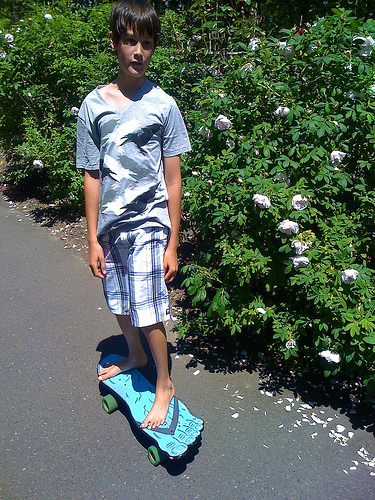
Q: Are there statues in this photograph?
A: No, there are no statues.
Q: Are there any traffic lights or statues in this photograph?
A: No, there are no statues or traffic lights.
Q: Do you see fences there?
A: No, there are no fences.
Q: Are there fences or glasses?
A: No, there are no fences or glasses.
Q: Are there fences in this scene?
A: No, there are no fences.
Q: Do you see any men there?
A: No, there are no men.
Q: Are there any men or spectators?
A: No, there are no men or spectators.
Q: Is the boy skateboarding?
A: Yes, the boy is skateboarding.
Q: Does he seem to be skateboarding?
A: Yes, the boy is skateboarding.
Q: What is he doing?
A: The boy is skateboarding.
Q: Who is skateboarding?
A: The boy is skateboarding.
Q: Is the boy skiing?
A: No, the boy is skateboarding.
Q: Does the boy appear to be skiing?
A: No, the boy is skateboarding.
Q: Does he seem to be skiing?
A: No, the boy is skateboarding.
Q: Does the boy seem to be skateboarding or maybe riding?
A: The boy is skateboarding.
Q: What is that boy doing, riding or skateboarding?
A: The boy is skateboarding.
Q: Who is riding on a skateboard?
A: The boy is riding on a skateboard.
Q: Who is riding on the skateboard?
A: The boy is riding on a skateboard.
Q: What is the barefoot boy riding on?
A: The boy is riding on a skateboard.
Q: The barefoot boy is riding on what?
A: The boy is riding on a skateboard.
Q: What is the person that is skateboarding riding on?
A: The boy is riding on a skateboard.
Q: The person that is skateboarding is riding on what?
A: The boy is riding on a skateboard.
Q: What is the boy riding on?
A: The boy is riding on a skateboard.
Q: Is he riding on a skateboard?
A: Yes, the boy is riding on a skateboard.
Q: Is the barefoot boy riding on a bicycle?
A: No, the boy is riding on a skateboard.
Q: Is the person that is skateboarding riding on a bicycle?
A: No, the boy is riding on a skateboard.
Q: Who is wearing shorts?
A: The boy is wearing shorts.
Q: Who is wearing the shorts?
A: The boy is wearing shorts.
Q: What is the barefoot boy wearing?
A: The boy is wearing shorts.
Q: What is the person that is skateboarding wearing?
A: The boy is wearing shorts.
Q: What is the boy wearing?
A: The boy is wearing shorts.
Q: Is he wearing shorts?
A: Yes, the boy is wearing shorts.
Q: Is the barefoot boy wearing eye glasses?
A: No, the boy is wearing shorts.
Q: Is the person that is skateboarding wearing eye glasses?
A: No, the boy is wearing shorts.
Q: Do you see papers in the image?
A: No, there are no papers.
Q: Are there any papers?
A: No, there are no papers.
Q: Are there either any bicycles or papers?
A: No, there are no papers or bicycles.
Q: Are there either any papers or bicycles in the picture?
A: No, there are no papers or bicycles.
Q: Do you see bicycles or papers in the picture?
A: No, there are no papers or bicycles.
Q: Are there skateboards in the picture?
A: Yes, there is a skateboard.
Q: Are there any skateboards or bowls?
A: Yes, there is a skateboard.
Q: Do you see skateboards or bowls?
A: Yes, there is a skateboard.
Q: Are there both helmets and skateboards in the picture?
A: No, there is a skateboard but no helmets.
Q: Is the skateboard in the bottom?
A: Yes, the skateboard is in the bottom of the image.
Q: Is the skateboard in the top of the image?
A: No, the skateboard is in the bottom of the image.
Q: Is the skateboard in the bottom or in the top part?
A: The skateboard is in the bottom of the image.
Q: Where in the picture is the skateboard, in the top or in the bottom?
A: The skateboard is in the bottom of the image.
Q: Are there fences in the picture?
A: No, there are no fences.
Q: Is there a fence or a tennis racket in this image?
A: No, there are no fences or rackets.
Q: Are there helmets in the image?
A: No, there are no helmets.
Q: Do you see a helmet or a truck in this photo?
A: No, there are no helmets or trucks.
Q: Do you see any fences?
A: No, there are no fences.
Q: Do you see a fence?
A: No, there are no fences.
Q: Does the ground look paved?
A: Yes, the ground is paved.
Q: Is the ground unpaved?
A: No, the ground is paved.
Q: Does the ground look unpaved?
A: No, the ground is paved.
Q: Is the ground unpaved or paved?
A: The ground is paved.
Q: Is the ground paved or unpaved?
A: The ground is paved.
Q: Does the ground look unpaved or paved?
A: The ground is paved.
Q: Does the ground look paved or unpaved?
A: The ground is paved.